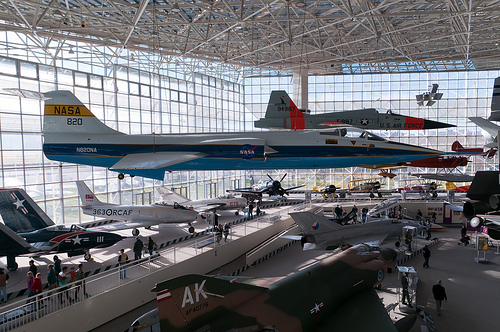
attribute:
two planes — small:
[67, 171, 267, 236]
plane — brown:
[132, 213, 424, 330]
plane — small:
[2, 186, 129, 261]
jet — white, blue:
[38, 55, 465, 188]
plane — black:
[28, 86, 463, 200]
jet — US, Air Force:
[251, 88, 458, 137]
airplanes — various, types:
[51, 41, 442, 193]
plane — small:
[76, 179, 199, 232]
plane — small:
[154, 185, 248, 215]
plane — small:
[1, 223, 131, 261]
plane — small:
[226, 172, 307, 198]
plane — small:
[344, 176, 399, 197]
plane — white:
[71, 183, 231, 252]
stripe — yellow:
[43, 140, 437, 159]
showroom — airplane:
[0, 0, 500, 330]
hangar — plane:
[28, 20, 458, 322]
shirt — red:
[22, 256, 42, 291]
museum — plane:
[8, 24, 491, 325]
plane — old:
[129, 238, 406, 326]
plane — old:
[242, 200, 441, 264]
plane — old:
[442, 166, 499, 257]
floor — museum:
[81, 202, 496, 330]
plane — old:
[226, 170, 314, 203]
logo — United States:
[293, 298, 341, 323]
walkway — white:
[25, 192, 313, 264]